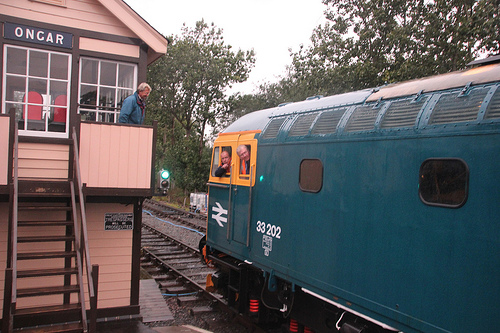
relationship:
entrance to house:
[2, 98, 93, 327] [1, 2, 173, 332]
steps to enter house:
[18, 181, 81, 329] [1, 2, 173, 332]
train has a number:
[195, 46, 500, 327] [252, 217, 288, 243]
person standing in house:
[113, 78, 154, 121] [1, 0, 173, 332]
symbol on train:
[259, 233, 275, 259] [195, 46, 500, 327]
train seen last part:
[195, 46, 500, 327] [182, 64, 323, 328]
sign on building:
[8, 19, 79, 57] [1, 2, 173, 332]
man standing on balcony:
[113, 78, 154, 121] [78, 114, 161, 204]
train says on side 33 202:
[195, 46, 500, 327] [252, 217, 288, 243]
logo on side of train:
[205, 195, 231, 231] [195, 46, 500, 327]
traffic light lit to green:
[156, 165, 173, 200] [157, 169, 172, 182]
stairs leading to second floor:
[2, 98, 93, 327] [0, 1, 178, 184]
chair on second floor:
[18, 88, 46, 128] [0, 1, 178, 184]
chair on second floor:
[49, 92, 69, 131] [0, 1, 178, 184]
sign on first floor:
[101, 212, 137, 232] [3, 193, 155, 332]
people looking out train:
[204, 141, 259, 184] [195, 46, 500, 327]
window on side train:
[412, 160, 467, 209] [195, 46, 500, 327]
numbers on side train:
[252, 217, 288, 243] [195, 46, 500, 327]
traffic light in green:
[156, 165, 173, 200] [157, 169, 172, 182]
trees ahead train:
[141, 0, 499, 192] [195, 46, 500, 327]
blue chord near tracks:
[144, 209, 208, 239] [147, 201, 222, 329]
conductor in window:
[211, 145, 233, 184] [203, 131, 236, 187]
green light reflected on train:
[254, 170, 269, 187] [195, 46, 500, 327]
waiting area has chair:
[3, 46, 124, 146] [18, 88, 45, 131]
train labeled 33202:
[195, 46, 500, 327] [252, 217, 288, 243]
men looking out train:
[204, 141, 259, 184] [195, 46, 500, 327]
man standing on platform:
[113, 78, 154, 121] [78, 114, 161, 204]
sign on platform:
[8, 19, 79, 57] [101, 212, 137, 232]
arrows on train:
[205, 195, 231, 231] [195, 46, 500, 327]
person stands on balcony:
[113, 78, 154, 121] [78, 114, 161, 204]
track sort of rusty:
[147, 201, 222, 329] [142, 216, 203, 286]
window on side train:
[412, 151, 474, 216] [195, 46, 500, 327]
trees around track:
[167, 1, 499, 78] [147, 201, 222, 329]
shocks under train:
[223, 278, 324, 332] [195, 46, 500, 327]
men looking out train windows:
[204, 141, 259, 184] [210, 133, 258, 188]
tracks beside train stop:
[147, 201, 222, 329] [12, 0, 168, 330]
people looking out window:
[204, 141, 259, 184] [210, 140, 258, 180]